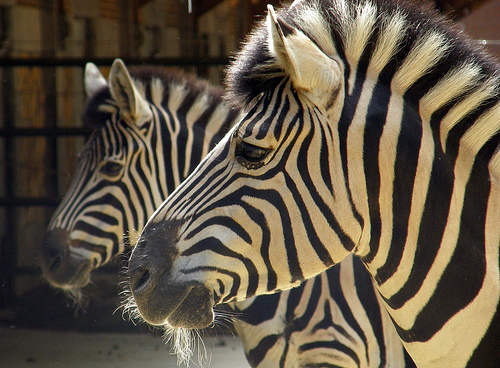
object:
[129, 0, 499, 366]
zebra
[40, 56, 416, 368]
zebra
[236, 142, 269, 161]
eye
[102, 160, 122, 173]
eye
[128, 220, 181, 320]
nose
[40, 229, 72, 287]
nose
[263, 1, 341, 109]
ear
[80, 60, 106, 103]
ear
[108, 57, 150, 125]
ear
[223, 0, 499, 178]
mane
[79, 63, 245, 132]
mane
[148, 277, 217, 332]
mouth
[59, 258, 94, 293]
mouth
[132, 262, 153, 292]
nostril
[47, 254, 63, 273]
nostril